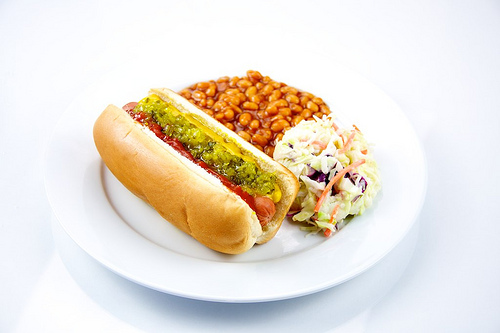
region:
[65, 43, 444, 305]
food on white ceramic plate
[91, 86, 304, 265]
hot dog with condiments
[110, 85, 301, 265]
hot dog with ketchup mustard and relish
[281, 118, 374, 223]
side of coleslaw on plate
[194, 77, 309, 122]
side of baked beans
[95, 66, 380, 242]
hot dog beans and coleslaw on plate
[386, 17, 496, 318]
stark white background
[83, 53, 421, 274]
full meal on white plate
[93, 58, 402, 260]
junk food with protein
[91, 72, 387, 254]
hot dog with side of beans and coleslaw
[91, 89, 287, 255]
hot dog on the plate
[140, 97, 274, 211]
relish on the hot dog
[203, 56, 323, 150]
bake beans next to hot dogs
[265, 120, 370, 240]
cole slaw next to the bake beans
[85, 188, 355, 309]
plate is white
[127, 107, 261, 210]
ketchup on the hot dog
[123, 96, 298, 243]
hot dog hasn't been bitten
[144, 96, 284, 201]
mustard next to the relish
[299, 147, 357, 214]
carrot in the cole slaw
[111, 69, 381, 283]
plate is full of food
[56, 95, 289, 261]
a hot dog on a plate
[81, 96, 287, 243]
a hot dog in a bun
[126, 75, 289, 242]
a hot dog with pickle relish on it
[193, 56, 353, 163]
beans on a plate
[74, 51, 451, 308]
food on a plate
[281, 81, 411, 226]
cold slaw on a plate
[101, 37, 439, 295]
a white plate with food on it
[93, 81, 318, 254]
a hot dog and beans on a plate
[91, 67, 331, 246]
a hot dog with mustard on it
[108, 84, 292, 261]
a hot dog with ketchup on it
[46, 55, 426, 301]
A white plate filled with food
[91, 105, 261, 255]
Top part of hot dog bun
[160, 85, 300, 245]
Bottom of the hot dog bun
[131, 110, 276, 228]
Hot dog in the middle of the hot dog bun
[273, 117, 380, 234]
Cold slaw on the white plate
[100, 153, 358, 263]
Middle of the white plate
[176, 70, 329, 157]
Baked beans next to the cold slaw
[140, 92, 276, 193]
Pickle relish on top of the hot dog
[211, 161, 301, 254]
Front end of hot dog and bun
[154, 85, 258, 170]
Mustard on the side of the pickle relish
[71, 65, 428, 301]
A white round plate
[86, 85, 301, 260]
Hot dog on a plate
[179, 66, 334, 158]
Brown beans on plate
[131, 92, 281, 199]
Sauer Kraut on hot dog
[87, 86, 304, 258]
A hot dog in a bun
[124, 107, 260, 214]
Ketchup on hot dog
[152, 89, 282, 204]
Mustard on the hot dog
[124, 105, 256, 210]
The ketchup is red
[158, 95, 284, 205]
The mustard is yellow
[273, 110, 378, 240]
Salad on the plate